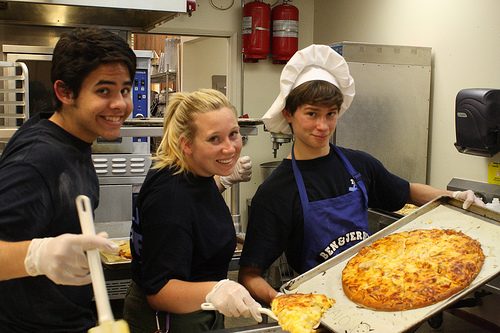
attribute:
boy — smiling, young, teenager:
[241, 82, 488, 303]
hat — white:
[259, 42, 358, 139]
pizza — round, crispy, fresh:
[341, 228, 483, 312]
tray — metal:
[281, 196, 499, 333]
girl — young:
[122, 89, 261, 332]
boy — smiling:
[2, 25, 137, 333]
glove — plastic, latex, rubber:
[25, 232, 119, 287]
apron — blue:
[291, 143, 369, 275]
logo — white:
[316, 230, 370, 259]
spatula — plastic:
[201, 303, 321, 327]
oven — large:
[2, 43, 152, 182]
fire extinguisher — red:
[272, 0, 300, 65]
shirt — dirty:
[1, 109, 101, 331]